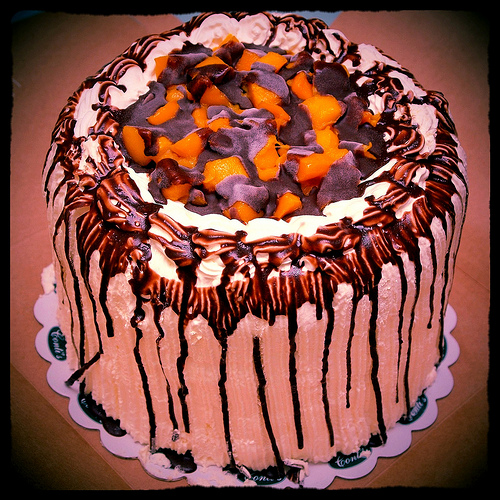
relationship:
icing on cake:
[118, 40, 381, 221] [38, 10, 468, 474]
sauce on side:
[64, 197, 430, 332] [43, 165, 454, 471]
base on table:
[29, 260, 462, 489] [12, 11, 484, 487]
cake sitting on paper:
[38, 10, 468, 474] [33, 259, 461, 489]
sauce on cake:
[181, 269, 192, 281] [38, 10, 468, 474]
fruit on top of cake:
[120, 31, 383, 222] [38, 10, 468, 474]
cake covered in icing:
[38, 10, 468, 474] [247, 216, 282, 234]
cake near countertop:
[38, 10, 468, 474] [9, 350, 484, 493]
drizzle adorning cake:
[287, 305, 304, 449] [38, 10, 468, 474]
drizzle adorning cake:
[285, 288, 303, 448] [38, 10, 468, 474]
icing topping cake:
[118, 40, 381, 221] [38, 10, 468, 474]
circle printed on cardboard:
[47, 325, 68, 362] [32, 290, 461, 489]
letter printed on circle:
[50, 327, 65, 340] [47, 325, 68, 362]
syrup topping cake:
[41, 9, 471, 472] [38, 10, 468, 474]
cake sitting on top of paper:
[38, 10, 468, 474] [34, 260, 460, 487]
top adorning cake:
[113, 34, 389, 222] [38, 10, 468, 474]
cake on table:
[42, 10, 467, 471] [4, 22, 119, 97]